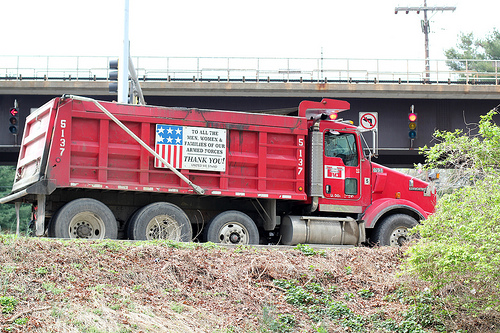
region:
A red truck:
[14, 77, 447, 282]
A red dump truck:
[10, 80, 429, 282]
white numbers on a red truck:
[28, 108, 110, 223]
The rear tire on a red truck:
[44, 188, 123, 272]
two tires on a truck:
[36, 183, 206, 275]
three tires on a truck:
[52, 186, 274, 260]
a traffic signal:
[394, 98, 424, 158]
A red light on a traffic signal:
[402, 99, 430, 131]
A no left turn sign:
[342, 96, 389, 155]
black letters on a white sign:
[182, 121, 246, 185]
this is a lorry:
[34, 92, 394, 228]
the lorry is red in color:
[236, 142, 278, 171]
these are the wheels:
[65, 196, 266, 241]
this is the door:
[325, 134, 356, 202]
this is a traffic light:
[6, 106, 17, 136]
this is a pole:
[117, 27, 132, 97]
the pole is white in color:
[116, 47, 128, 95]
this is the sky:
[151, 18, 238, 50]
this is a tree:
[463, 26, 498, 68]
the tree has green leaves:
[477, 38, 497, 58]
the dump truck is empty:
[12, 90, 438, 250]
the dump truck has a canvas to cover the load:
[32, 87, 207, 202]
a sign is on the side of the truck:
[153, 121, 228, 177]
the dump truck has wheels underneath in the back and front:
[54, 190, 429, 262]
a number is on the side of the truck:
[292, 123, 304, 200]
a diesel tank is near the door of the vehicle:
[283, 200, 371, 249]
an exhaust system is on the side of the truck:
[306, 107, 328, 216]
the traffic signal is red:
[402, 101, 421, 152]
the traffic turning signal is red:
[3, 98, 21, 141]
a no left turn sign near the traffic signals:
[357, 107, 380, 163]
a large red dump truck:
[0, 51, 439, 270]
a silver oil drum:
[278, 211, 375, 262]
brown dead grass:
[94, 252, 176, 294]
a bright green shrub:
[416, 137, 498, 284]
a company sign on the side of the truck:
[156, 122, 231, 179]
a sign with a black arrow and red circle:
[356, 107, 386, 138]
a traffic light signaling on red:
[398, 100, 430, 154]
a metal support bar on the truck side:
[92, 100, 109, 117]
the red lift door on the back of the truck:
[11, 115, 42, 180]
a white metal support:
[122, 7, 133, 99]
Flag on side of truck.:
[153, 125, 204, 234]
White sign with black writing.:
[187, 108, 251, 210]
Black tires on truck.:
[51, 192, 230, 272]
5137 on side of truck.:
[52, 114, 84, 185]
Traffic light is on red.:
[400, 83, 411, 222]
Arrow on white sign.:
[352, 94, 399, 187]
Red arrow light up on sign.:
[3, 104, 40, 146]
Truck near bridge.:
[209, 65, 417, 139]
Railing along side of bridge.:
[228, 60, 459, 79]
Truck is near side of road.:
[64, 185, 494, 280]